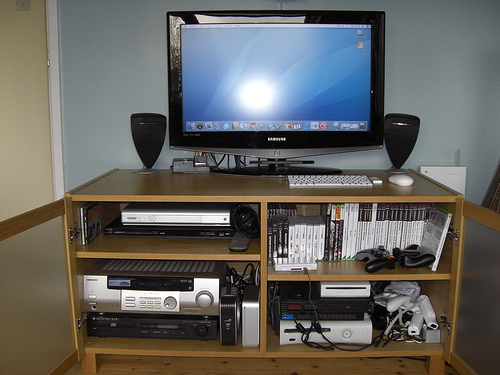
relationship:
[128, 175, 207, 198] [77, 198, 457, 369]
wooden entertainment center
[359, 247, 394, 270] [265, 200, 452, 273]
controller on shelf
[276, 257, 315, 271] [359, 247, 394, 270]
white game controller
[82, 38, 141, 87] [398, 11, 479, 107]
blue painted wall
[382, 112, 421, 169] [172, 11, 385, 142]
speakers near screen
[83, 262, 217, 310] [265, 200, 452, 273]
stereo on shelf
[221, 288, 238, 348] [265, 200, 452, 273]
router on shelf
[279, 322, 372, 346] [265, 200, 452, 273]
console on shelf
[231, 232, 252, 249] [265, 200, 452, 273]
remote on shelf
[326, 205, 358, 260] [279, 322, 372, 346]
games for console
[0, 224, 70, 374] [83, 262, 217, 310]
doors of stereo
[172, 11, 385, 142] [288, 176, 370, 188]
computer wireless keyboard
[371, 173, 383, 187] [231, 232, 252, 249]
white apple remote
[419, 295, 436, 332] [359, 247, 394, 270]
wii game controller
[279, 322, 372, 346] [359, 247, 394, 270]
xbox game controller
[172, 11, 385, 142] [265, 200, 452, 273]
tv on shelf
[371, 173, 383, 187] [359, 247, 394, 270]
white xbox controller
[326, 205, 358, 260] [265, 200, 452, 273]
games on shelf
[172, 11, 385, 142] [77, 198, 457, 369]
tv on system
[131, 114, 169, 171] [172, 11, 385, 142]
speaker near tv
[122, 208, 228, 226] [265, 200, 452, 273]
dvd on shelf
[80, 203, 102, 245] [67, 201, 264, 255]
dvd on shelf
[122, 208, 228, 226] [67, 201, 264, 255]
dvd on top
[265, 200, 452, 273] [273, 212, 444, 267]
shelf with game